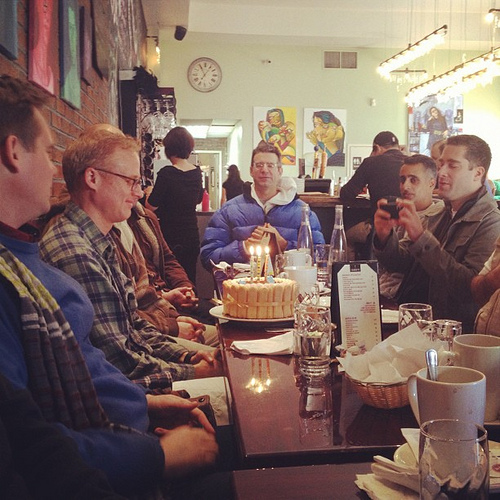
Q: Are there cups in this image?
A: Yes, there is a cup.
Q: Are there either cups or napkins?
A: Yes, there is a cup.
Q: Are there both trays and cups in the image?
A: No, there is a cup but no trays.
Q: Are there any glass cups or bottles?
A: Yes, there is a glass cup.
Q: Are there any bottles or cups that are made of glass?
A: Yes, the cup is made of glass.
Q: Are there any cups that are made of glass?
A: Yes, there is a cup that is made of glass.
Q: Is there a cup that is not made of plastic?
A: Yes, there is a cup that is made of glass.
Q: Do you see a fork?
A: No, there are no forks.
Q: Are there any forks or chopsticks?
A: No, there are no forks or chopsticks.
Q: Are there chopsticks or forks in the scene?
A: No, there are no forks or chopsticks.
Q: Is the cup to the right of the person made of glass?
A: Yes, the cup is made of glass.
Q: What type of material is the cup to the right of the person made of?
A: The cup is made of glass.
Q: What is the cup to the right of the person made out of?
A: The cup is made of glass.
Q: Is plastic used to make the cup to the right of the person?
A: No, the cup is made of glass.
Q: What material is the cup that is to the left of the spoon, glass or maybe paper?
A: The cup is made of glass.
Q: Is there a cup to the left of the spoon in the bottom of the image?
A: Yes, there is a cup to the left of the spoon.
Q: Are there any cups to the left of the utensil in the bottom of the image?
A: Yes, there is a cup to the left of the spoon.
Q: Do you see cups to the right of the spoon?
A: No, the cup is to the left of the spoon.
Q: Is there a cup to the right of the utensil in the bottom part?
A: No, the cup is to the left of the spoon.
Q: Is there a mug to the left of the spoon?
A: No, there is a cup to the left of the spoon.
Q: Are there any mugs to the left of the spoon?
A: No, there is a cup to the left of the spoon.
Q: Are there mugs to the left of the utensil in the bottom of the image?
A: No, there is a cup to the left of the spoon.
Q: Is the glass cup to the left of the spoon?
A: Yes, the cup is to the left of the spoon.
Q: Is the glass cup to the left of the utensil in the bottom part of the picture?
A: Yes, the cup is to the left of the spoon.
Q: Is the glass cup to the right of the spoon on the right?
A: No, the cup is to the left of the spoon.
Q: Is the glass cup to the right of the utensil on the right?
A: No, the cup is to the left of the spoon.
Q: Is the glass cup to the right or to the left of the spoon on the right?
A: The cup is to the left of the spoon.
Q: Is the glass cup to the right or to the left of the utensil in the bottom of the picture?
A: The cup is to the left of the spoon.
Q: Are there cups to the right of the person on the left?
A: Yes, there is a cup to the right of the person.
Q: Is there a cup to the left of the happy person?
A: No, the cup is to the right of the person.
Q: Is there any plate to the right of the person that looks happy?
A: No, there is a cup to the right of the person.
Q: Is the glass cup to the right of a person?
A: Yes, the cup is to the right of a person.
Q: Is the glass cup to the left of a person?
A: No, the cup is to the right of a person.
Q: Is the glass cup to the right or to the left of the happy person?
A: The cup is to the right of the person.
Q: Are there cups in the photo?
A: Yes, there is a cup.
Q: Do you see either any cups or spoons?
A: Yes, there is a cup.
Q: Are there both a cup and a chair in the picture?
A: No, there is a cup but no chairs.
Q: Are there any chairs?
A: No, there are no chairs.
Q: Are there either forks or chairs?
A: No, there are no chairs or forks.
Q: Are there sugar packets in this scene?
A: No, there are no sugar packets.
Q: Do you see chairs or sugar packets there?
A: No, there are no sugar packets or chairs.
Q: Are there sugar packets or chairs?
A: No, there are no sugar packets or chairs.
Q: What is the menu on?
A: The menu is on the table.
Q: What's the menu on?
A: The menu is on the table.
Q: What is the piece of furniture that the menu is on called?
A: The piece of furniture is a table.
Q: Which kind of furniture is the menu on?
A: The menu is on the table.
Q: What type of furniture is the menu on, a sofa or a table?
A: The menu is on a table.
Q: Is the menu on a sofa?
A: No, the menu is on the table.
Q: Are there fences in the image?
A: No, there are no fences.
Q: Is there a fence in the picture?
A: No, there are no fences.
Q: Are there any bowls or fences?
A: No, there are no fences or bowls.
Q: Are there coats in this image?
A: Yes, there is a coat.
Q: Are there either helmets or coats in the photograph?
A: Yes, there is a coat.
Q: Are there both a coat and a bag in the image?
A: No, there is a coat but no bags.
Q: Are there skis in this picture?
A: No, there are no skis.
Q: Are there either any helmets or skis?
A: No, there are no skis or helmets.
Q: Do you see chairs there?
A: No, there are no chairs.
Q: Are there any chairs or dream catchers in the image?
A: No, there are no chairs or dream catchers.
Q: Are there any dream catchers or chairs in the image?
A: No, there are no chairs or dream catchers.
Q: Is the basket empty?
A: Yes, the basket is empty.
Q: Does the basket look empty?
A: Yes, the basket is empty.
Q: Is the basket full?
A: No, the basket is empty.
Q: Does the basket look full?
A: No, the basket is empty.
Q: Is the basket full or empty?
A: The basket is empty.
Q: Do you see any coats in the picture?
A: Yes, there is a coat.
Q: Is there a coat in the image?
A: Yes, there is a coat.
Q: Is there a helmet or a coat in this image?
A: Yes, there is a coat.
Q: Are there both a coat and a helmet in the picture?
A: No, there is a coat but no helmets.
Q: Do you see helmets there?
A: No, there are no helmets.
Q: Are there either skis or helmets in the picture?
A: No, there are no helmets or skis.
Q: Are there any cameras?
A: Yes, there is a camera.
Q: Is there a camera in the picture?
A: Yes, there is a camera.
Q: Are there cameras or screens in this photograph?
A: Yes, there is a camera.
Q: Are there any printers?
A: No, there are no printers.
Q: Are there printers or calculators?
A: No, there are no printers or calculators.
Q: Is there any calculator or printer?
A: No, there are no printers or calculators.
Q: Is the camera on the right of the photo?
A: Yes, the camera is on the right of the image.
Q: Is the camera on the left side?
A: No, the camera is on the right of the image.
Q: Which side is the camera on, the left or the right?
A: The camera is on the right of the image.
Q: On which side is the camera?
A: The camera is on the right of the image.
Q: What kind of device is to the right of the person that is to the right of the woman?
A: The device is a camera.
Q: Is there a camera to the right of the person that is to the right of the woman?
A: Yes, there is a camera to the right of the person.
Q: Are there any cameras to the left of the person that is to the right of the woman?
A: No, the camera is to the right of the person.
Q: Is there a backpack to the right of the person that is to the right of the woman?
A: No, there is a camera to the right of the person.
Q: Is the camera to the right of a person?
A: Yes, the camera is to the right of a person.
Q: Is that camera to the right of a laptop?
A: No, the camera is to the right of a person.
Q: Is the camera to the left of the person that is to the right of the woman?
A: No, the camera is to the right of the person.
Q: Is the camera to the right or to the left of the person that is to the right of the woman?
A: The camera is to the right of the person.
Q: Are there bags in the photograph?
A: No, there are no bags.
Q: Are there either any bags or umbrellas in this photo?
A: No, there are no bags or umbrellas.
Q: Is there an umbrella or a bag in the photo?
A: No, there are no bags or umbrellas.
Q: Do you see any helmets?
A: No, there are no helmets.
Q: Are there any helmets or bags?
A: No, there are no helmets or bags.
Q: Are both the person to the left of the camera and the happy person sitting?
A: Yes, both the person and the person are sitting.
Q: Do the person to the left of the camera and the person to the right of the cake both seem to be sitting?
A: Yes, both the person and the person are sitting.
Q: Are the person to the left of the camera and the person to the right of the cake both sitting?
A: Yes, both the person and the person are sitting.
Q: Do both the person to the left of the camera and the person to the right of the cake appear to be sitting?
A: Yes, both the person and the person are sitting.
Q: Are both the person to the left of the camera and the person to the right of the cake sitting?
A: Yes, both the person and the person are sitting.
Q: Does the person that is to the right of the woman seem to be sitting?
A: Yes, the person is sitting.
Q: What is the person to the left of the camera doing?
A: The person is sitting.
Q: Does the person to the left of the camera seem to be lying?
A: No, the person is sitting.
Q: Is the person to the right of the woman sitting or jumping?
A: The person is sitting.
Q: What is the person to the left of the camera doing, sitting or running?
A: The person is sitting.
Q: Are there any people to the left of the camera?
A: Yes, there is a person to the left of the camera.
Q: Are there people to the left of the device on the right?
A: Yes, there is a person to the left of the camera.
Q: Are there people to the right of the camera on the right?
A: No, the person is to the left of the camera.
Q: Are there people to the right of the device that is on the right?
A: No, the person is to the left of the camera.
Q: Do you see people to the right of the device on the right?
A: No, the person is to the left of the camera.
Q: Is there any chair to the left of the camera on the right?
A: No, there is a person to the left of the camera.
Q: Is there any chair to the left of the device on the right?
A: No, there is a person to the left of the camera.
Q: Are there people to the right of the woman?
A: Yes, there is a person to the right of the woman.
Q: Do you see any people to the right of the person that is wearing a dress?
A: Yes, there is a person to the right of the woman.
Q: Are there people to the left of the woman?
A: No, the person is to the right of the woman.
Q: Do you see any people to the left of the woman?
A: No, the person is to the right of the woman.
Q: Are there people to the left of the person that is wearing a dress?
A: No, the person is to the right of the woman.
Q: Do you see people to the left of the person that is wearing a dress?
A: No, the person is to the right of the woman.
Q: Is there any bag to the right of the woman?
A: No, there is a person to the right of the woman.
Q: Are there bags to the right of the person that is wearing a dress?
A: No, there is a person to the right of the woman.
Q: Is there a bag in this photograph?
A: No, there are no bags.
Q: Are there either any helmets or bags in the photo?
A: No, there are no bags or helmets.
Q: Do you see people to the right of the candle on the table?
A: Yes, there is a person to the right of the candle.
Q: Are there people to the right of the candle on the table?
A: Yes, there is a person to the right of the candle.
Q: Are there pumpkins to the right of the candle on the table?
A: No, there is a person to the right of the candle.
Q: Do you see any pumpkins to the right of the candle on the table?
A: No, there is a person to the right of the candle.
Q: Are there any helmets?
A: No, there are no helmets.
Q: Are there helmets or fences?
A: No, there are no helmets or fences.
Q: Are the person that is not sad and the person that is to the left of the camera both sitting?
A: Yes, both the person and the person are sitting.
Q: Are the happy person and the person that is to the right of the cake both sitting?
A: Yes, both the person and the person are sitting.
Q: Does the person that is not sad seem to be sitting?
A: Yes, the person is sitting.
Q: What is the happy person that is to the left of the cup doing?
A: The person is sitting.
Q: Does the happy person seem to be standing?
A: No, the person is sitting.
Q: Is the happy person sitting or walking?
A: The person is sitting.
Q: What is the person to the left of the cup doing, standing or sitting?
A: The person is sitting.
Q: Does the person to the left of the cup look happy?
A: Yes, the person is happy.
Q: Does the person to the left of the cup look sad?
A: No, the person is happy.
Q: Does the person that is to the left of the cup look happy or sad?
A: The person is happy.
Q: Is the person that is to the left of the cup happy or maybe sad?
A: The person is happy.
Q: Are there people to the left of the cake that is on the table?
A: Yes, there is a person to the left of the cake.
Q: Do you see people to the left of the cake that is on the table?
A: Yes, there is a person to the left of the cake.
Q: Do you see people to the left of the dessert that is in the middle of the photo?
A: Yes, there is a person to the left of the cake.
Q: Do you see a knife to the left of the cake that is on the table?
A: No, there is a person to the left of the cake.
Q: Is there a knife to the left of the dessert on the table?
A: No, there is a person to the left of the cake.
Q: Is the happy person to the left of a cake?
A: Yes, the person is to the left of a cake.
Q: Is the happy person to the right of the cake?
A: No, the person is to the left of the cake.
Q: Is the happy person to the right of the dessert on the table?
A: No, the person is to the left of the cake.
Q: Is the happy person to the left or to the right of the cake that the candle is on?
A: The person is to the left of the cake.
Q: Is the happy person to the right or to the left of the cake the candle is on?
A: The person is to the left of the cake.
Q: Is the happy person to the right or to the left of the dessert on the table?
A: The person is to the left of the cake.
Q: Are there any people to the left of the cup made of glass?
A: Yes, there is a person to the left of the cup.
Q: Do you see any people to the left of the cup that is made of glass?
A: Yes, there is a person to the left of the cup.